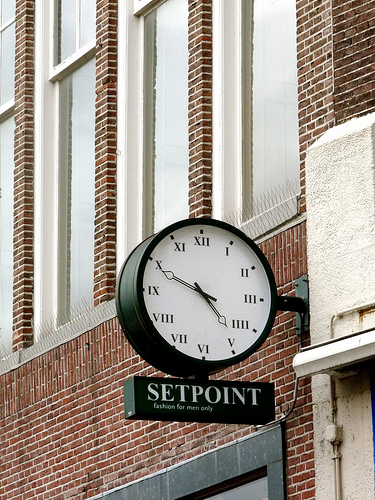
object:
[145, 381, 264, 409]
letters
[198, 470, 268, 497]
glass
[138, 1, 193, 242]
window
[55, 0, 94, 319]
window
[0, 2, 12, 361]
window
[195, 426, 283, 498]
black slate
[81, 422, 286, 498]
trim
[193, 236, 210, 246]
roman numberal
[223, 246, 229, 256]
roman numberal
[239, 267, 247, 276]
roman numberal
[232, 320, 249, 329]
roman numberal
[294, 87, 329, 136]
ground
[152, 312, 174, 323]
roman numeral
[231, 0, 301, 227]
windows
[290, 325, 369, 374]
frame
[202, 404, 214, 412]
word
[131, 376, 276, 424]
sign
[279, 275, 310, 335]
bracket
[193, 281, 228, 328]
hand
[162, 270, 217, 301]
hand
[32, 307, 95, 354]
sill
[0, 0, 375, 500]
bricks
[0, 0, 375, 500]
building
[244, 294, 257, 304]
numerals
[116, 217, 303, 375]
clock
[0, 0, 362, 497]
wall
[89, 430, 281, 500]
door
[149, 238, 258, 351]
numerals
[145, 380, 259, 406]
word